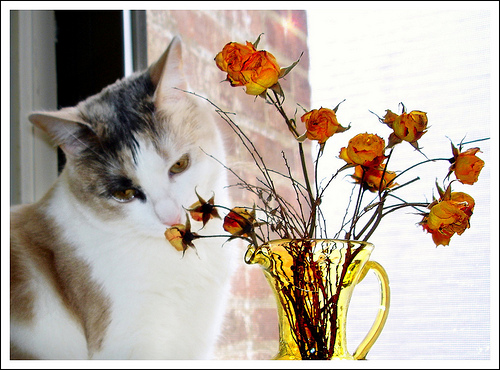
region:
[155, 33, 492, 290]
THE ROSES ARE ORANGE AND YELLOW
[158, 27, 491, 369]
THE FLOWERS ARE ROSES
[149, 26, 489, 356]
THE ROSES ARE IN A PITCHER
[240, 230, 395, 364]
THE PITCHER IS CLEAR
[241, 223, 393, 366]
THE PITCHER IS GLASS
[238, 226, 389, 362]
THE PITCHER IS YELLOW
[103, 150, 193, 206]
THE CAT HAS GREEN EYES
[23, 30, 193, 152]
THE CAT HAS TWO EARS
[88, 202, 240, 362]
THE CAT HAS A WHITE CHEST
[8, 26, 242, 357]
THE CAT IS IN A WINDOW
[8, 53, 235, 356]
a white brown a black cat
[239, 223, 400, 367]
a yellow glass vase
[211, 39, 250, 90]
an orange rose bud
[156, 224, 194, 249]
an orange rose bud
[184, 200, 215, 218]
an orange rose bud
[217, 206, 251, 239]
an orange rose bud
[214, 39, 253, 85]
an orange rose flower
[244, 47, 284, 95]
an orange rose flower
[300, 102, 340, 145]
an orange rose flower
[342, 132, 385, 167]
an orange rose flower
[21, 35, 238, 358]
the multi colored cat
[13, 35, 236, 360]
the cat sitting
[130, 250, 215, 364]
the white part on the cat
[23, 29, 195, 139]
the cat's ears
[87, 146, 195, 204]
the cat's yellow eyes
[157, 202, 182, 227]
the cat's pink nose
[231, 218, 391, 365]
the yellow glass vase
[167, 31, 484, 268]
the roses in the vase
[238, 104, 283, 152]
the red brick wall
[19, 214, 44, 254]
the brown on the cat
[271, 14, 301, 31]
small shine on the wall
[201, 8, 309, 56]
red bricks on wall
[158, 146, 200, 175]
cat's beautiful green eyes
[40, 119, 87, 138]
fur in cat's ear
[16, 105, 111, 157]
cat's upturned ears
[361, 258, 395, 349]
gold handle on vase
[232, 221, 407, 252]
lid on gold vase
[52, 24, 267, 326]
furry white tabby cat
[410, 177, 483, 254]
orange flower in vase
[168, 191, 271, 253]
black stem on orange flowers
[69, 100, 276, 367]
a cat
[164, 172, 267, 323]
a cat